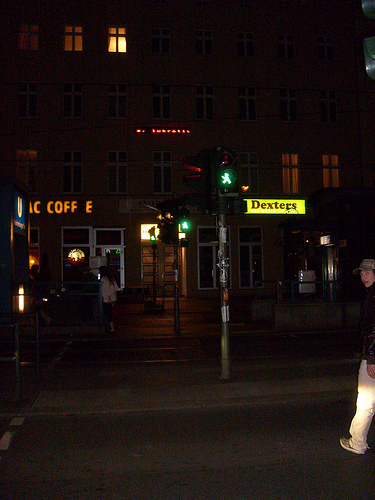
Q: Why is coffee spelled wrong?
A: The bulb in the first E is burned out.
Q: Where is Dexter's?
A: On the right side of the building.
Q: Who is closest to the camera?
A: A man in white pants.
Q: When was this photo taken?
A: At night.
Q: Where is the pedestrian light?
A: On a pole.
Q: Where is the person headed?
A: Crossing road.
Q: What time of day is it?
A: Night.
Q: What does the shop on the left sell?
A: Coffee.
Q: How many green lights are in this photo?
A: 3.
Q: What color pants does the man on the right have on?
A: White.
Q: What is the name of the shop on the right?
A: Dexters.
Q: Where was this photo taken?
A: On a Street.